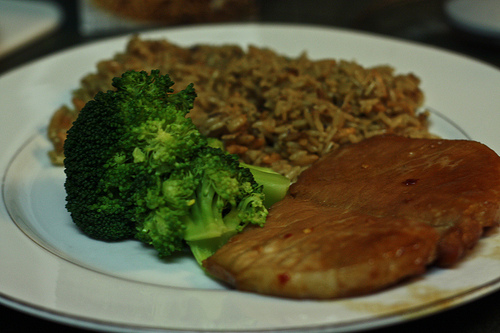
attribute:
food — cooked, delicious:
[46, 34, 498, 304]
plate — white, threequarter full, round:
[4, 23, 499, 329]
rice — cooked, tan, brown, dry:
[47, 33, 442, 183]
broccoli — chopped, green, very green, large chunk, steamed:
[63, 68, 269, 265]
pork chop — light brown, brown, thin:
[201, 132, 499, 300]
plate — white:
[2, 1, 60, 57]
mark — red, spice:
[278, 272, 290, 284]